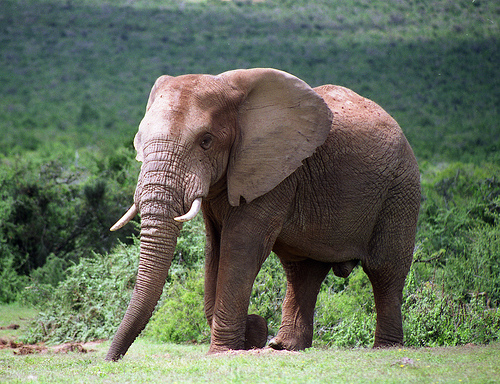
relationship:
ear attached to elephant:
[223, 63, 329, 220] [106, 62, 424, 351]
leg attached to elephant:
[206, 209, 283, 356] [124, 69, 419, 338]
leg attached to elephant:
[275, 257, 321, 359] [106, 62, 424, 351]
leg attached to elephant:
[364, 175, 411, 345] [124, 69, 419, 338]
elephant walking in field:
[106, 62, 424, 351] [0, 291, 497, 381]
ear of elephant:
[223, 66, 334, 206] [106, 62, 424, 351]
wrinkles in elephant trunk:
[134, 173, 177, 274] [101, 173, 181, 367]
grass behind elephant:
[0, 163, 499, 378] [87, 61, 400, 329]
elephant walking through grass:
[102, 67, 421, 364] [7, 311, 481, 371]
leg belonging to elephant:
[200, 209, 270, 349] [106, 62, 424, 351]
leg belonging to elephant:
[206, 209, 283, 356] [106, 62, 424, 351]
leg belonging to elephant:
[266, 257, 321, 351] [106, 62, 424, 351]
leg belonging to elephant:
[364, 175, 419, 348] [106, 62, 424, 351]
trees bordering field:
[0, 136, 495, 340] [5, 311, 497, 380]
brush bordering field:
[33, 218, 492, 336] [5, 311, 497, 380]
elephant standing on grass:
[106, 62, 424, 351] [1, 338, 499, 382]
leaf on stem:
[434, 320, 459, 346] [411, 263, 498, 353]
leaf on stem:
[360, 338, 372, 349] [351, 330, 361, 341]